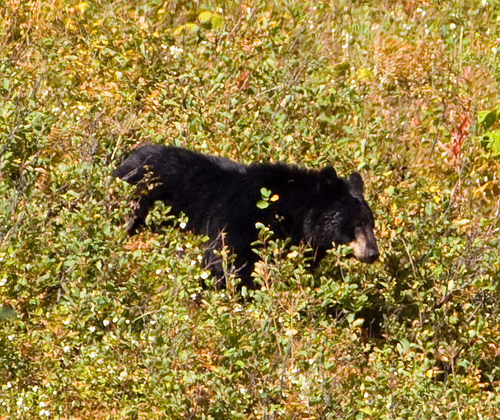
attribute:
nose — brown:
[364, 248, 378, 261]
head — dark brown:
[301, 166, 379, 262]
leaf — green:
[224, 340, 248, 359]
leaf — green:
[233, 357, 249, 369]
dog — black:
[73, 98, 447, 315]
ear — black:
[347, 169, 372, 200]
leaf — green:
[345, 307, 355, 326]